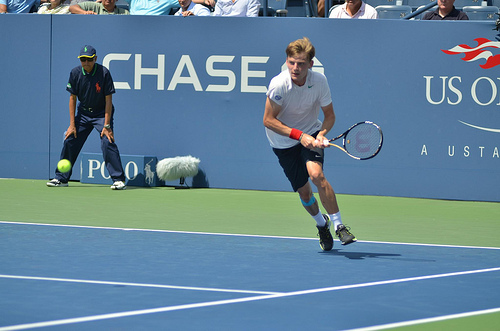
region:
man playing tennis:
[245, 29, 397, 259]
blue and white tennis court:
[78, 218, 132, 278]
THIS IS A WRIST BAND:
[286, 123, 311, 145]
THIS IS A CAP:
[77, 40, 96, 60]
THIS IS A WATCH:
[102, 119, 113, 130]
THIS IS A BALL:
[49, 151, 76, 173]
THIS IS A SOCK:
[329, 210, 341, 232]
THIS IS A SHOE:
[334, 220, 354, 247]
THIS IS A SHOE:
[314, 225, 336, 250]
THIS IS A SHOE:
[108, 175, 132, 191]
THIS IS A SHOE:
[48, 176, 65, 188]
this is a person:
[438, 0, 463, 26]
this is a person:
[339, 0, 374, 18]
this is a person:
[212, 0, 256, 20]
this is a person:
[124, 2, 177, 14]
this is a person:
[92, 0, 127, 14]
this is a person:
[38, 3, 84, 11]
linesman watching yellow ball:
[47, 40, 133, 191]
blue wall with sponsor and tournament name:
[5, 17, 497, 199]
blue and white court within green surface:
[2, 172, 498, 327]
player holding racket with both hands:
[258, 37, 386, 169]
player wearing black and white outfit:
[262, 35, 333, 192]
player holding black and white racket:
[308, 117, 384, 162]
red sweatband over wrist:
[284, 126, 316, 149]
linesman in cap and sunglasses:
[72, 43, 98, 73]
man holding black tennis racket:
[324, 119, 384, 161]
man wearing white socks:
[315, 209, 340, 228]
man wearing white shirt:
[263, 65, 338, 146]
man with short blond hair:
[283, 35, 320, 92]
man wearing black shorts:
[273, 133, 327, 201]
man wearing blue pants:
[51, 115, 123, 180]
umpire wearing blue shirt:
[66, 65, 113, 116]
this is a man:
[243, 18, 408, 288]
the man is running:
[203, 23, 459, 288]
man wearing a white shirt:
[246, 63, 347, 163]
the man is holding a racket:
[306, 122, 386, 162]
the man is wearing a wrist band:
[287, 125, 303, 142]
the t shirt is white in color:
[264, 70, 331, 151]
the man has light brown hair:
[285, 37, 318, 62]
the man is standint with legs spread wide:
[40, 49, 130, 186]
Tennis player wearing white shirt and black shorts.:
[260, 36, 357, 253]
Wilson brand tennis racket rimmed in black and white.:
[323, 119, 385, 159]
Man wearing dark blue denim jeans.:
[48, 43, 128, 190]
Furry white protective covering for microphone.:
[154, 155, 203, 182]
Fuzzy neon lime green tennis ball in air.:
[55, 158, 69, 174]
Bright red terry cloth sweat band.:
[287, 126, 303, 138]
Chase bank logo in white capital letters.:
[102, 52, 270, 92]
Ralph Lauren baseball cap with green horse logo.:
[76, 43, 97, 59]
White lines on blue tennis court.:
[1, 214, 498, 329]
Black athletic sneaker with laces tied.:
[334, 223, 356, 245]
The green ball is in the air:
[54, 151, 73, 177]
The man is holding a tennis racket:
[248, 22, 404, 267]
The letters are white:
[82, 35, 286, 119]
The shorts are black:
[259, 121, 370, 214]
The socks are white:
[294, 205, 371, 241]